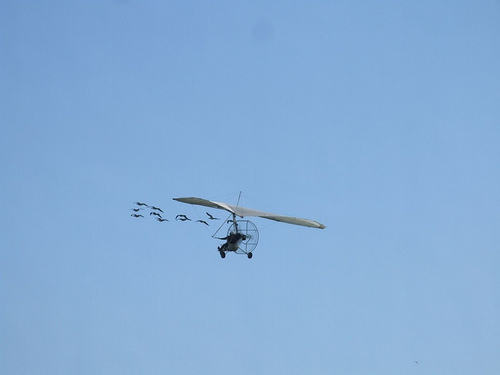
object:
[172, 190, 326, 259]
plane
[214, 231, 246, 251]
man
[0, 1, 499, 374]
sky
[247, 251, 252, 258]
wheels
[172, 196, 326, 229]
wings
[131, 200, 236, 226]
birds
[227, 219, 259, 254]
fan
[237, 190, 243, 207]
bar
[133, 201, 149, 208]
wings